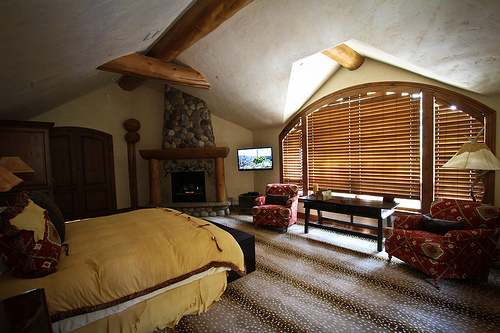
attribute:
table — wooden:
[298, 186, 395, 258]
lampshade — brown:
[441, 141, 499, 174]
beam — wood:
[320, 42, 363, 69]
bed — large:
[19, 198, 251, 330]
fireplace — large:
[153, 88, 229, 210]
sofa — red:
[249, 180, 305, 232]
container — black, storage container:
[200, 215, 257, 282]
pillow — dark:
[418, 210, 461, 236]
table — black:
[301, 187, 403, 253]